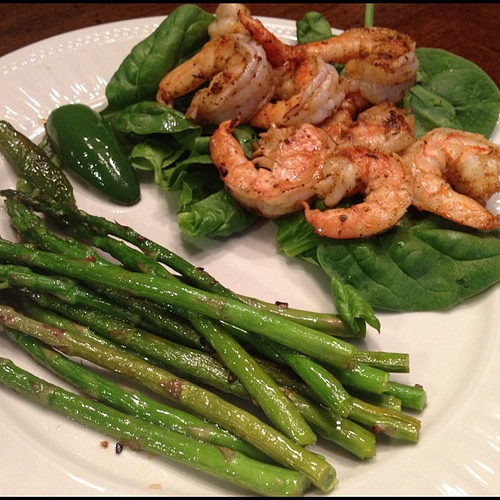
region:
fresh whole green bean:
[1, 358, 300, 493]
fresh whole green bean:
[25, 288, 375, 463]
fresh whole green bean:
[6, 262, 138, 321]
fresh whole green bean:
[2, 240, 362, 370]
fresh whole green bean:
[274, 342, 354, 419]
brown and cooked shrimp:
[194, 23, 471, 274]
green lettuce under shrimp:
[182, 33, 490, 294]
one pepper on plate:
[50, 101, 142, 211]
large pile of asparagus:
[22, 203, 369, 464]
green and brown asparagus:
[7, 183, 369, 468]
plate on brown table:
[11, 0, 491, 490]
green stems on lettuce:
[332, 3, 407, 47]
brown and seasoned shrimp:
[161, 21, 493, 252]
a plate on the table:
[1, 14, 486, 489]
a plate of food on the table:
[8, 10, 490, 490]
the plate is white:
[5, 36, 493, 495]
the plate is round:
[1, 3, 490, 488]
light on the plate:
[424, 438, 491, 498]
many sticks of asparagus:
[1, 196, 417, 473]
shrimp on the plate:
[146, 2, 477, 267]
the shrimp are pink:
[228, 87, 476, 263]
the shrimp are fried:
[206, 21, 481, 257]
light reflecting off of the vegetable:
[57, 118, 145, 216]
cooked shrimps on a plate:
[157, 3, 497, 234]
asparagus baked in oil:
[3, 188, 423, 489]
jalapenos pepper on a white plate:
[41, 102, 142, 203]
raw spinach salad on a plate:
[98, 4, 498, 334]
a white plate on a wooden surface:
[0, 12, 495, 497]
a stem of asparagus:
[0, 238, 359, 367]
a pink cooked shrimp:
[211, 115, 321, 217]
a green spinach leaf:
[101, 2, 213, 112]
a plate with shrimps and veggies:
[0, 3, 497, 498]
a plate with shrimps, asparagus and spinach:
[4, 13, 491, 496]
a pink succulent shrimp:
[209, 120, 334, 219]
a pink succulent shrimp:
[303, 145, 414, 239]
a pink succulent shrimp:
[402, 125, 499, 232]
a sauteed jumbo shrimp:
[158, 33, 267, 123]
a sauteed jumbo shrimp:
[253, 58, 344, 127]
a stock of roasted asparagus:
[0, 238, 358, 365]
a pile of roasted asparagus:
[0, 197, 425, 497]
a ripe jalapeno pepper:
[45, 102, 138, 205]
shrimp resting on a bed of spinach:
[103, 0, 499, 329]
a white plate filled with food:
[1, 12, 498, 499]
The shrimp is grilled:
[208, 116, 325, 217]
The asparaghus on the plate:
[0, 241, 365, 370]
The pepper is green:
[44, 95, 144, 204]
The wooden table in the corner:
[259, 3, 499, 89]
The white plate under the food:
[1, 17, 499, 497]